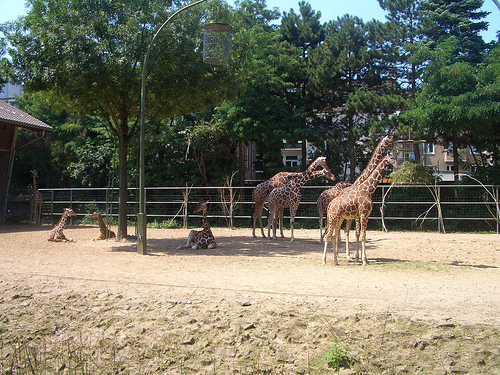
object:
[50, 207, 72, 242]
giraffe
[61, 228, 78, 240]
leg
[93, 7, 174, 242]
tree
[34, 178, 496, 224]
fence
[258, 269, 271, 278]
dirt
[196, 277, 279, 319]
ground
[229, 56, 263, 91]
leaf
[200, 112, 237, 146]
plant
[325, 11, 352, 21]
sun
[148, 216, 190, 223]
grass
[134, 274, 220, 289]
sand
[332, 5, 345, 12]
ligh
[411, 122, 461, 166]
building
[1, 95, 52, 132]
roof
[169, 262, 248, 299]
part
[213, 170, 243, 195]
part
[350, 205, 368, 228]
part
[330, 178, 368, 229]
stomach